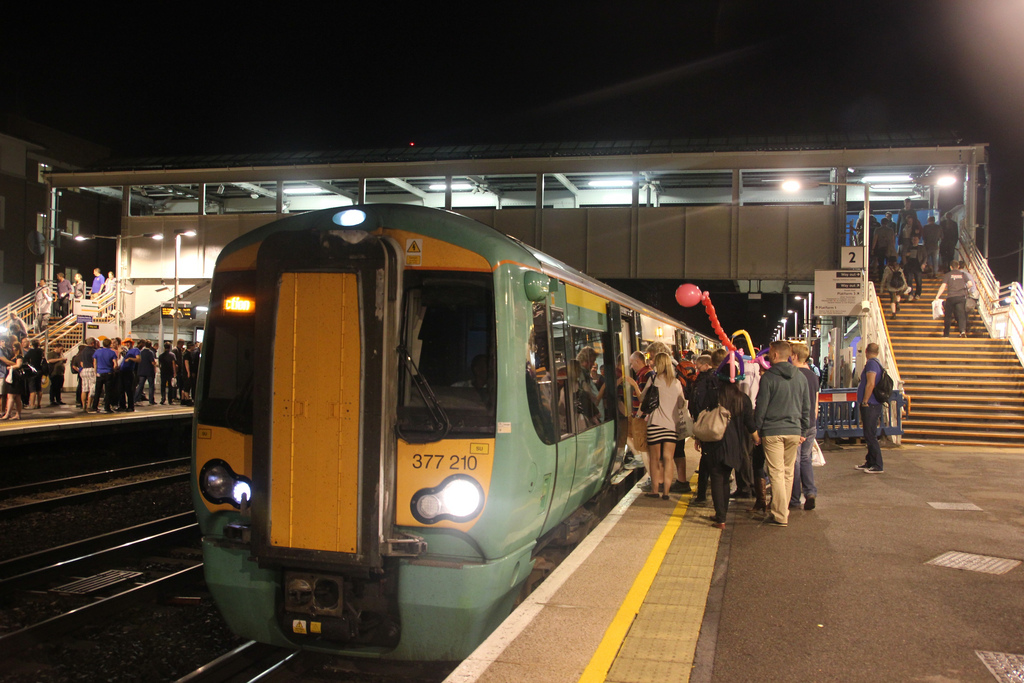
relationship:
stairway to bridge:
[845, 261, 1014, 435] [54, 160, 975, 275]